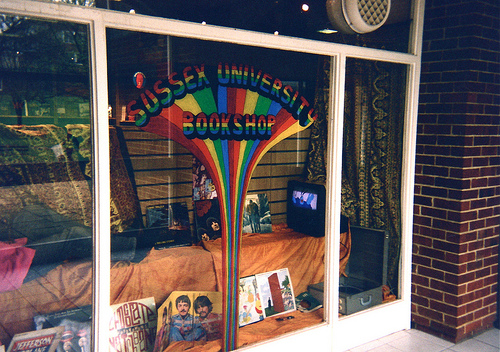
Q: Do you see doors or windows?
A: Yes, there is a window.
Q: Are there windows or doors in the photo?
A: Yes, there is a window.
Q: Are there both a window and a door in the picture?
A: No, there is a window but no doors.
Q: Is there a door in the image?
A: No, there are no doors.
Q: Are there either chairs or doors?
A: No, there are no doors or chairs.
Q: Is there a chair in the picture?
A: No, there are no chairs.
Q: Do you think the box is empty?
A: Yes, the box is empty.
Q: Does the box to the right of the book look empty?
A: Yes, the box is empty.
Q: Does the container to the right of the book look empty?
A: Yes, the box is empty.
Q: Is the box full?
A: No, the box is empty.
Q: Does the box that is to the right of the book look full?
A: No, the box is empty.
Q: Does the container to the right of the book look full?
A: No, the box is empty.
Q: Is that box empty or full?
A: The box is empty.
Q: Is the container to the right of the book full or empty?
A: The box is empty.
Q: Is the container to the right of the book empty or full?
A: The box is empty.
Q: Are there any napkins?
A: No, there are no napkins.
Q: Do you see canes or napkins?
A: No, there are no napkins or canes.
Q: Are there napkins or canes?
A: No, there are no napkins or canes.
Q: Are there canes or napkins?
A: No, there are no napkins or canes.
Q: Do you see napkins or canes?
A: No, there are no napkins or canes.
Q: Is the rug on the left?
A: Yes, the rug is on the left of the image.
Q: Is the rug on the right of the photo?
A: No, the rug is on the left of the image.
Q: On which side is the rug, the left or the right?
A: The rug is on the left of the image.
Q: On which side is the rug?
A: The rug is on the left of the image.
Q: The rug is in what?
A: The rug is in the window.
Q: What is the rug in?
A: The rug is in the window.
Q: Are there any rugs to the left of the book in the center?
A: Yes, there is a rug to the left of the book.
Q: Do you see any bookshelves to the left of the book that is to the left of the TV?
A: No, there is a rug to the left of the book.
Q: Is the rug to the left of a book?
A: Yes, the rug is to the left of a book.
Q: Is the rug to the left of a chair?
A: No, the rug is to the left of a book.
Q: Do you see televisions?
A: Yes, there is a television.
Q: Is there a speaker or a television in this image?
A: Yes, there is a television.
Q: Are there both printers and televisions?
A: No, there is a television but no printers.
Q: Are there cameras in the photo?
A: No, there are no cameras.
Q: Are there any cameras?
A: No, there are no cameras.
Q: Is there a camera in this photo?
A: No, there are no cameras.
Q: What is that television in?
A: The television is in the window.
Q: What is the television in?
A: The television is in the window.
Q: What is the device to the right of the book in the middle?
A: The device is a television.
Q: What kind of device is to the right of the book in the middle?
A: The device is a television.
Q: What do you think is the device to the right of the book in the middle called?
A: The device is a television.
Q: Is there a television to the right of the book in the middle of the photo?
A: Yes, there is a television to the right of the book.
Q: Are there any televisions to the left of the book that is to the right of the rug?
A: No, the television is to the right of the book.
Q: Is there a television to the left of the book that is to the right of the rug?
A: No, the television is to the right of the book.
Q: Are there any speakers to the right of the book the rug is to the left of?
A: No, there is a television to the right of the book.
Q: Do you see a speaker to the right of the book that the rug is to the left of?
A: No, there is a television to the right of the book.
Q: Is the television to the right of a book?
A: Yes, the television is to the right of a book.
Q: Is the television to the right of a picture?
A: No, the television is to the right of a book.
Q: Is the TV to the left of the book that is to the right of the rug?
A: No, the TV is to the right of the book.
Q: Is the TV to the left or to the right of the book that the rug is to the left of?
A: The TV is to the right of the book.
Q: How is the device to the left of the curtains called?
A: The device is a television.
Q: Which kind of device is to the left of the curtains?
A: The device is a television.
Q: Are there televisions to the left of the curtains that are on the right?
A: Yes, there is a television to the left of the curtains.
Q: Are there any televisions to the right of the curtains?
A: No, the television is to the left of the curtains.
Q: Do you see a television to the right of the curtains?
A: No, the television is to the left of the curtains.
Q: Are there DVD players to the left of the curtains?
A: No, there is a television to the left of the curtains.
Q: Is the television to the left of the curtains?
A: Yes, the television is to the left of the curtains.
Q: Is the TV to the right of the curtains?
A: No, the TV is to the left of the curtains.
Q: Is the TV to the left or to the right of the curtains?
A: The TV is to the left of the curtains.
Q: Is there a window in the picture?
A: Yes, there is a window.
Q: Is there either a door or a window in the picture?
A: Yes, there is a window.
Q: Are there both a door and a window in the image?
A: No, there is a window but no doors.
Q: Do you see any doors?
A: No, there are no doors.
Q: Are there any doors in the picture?
A: No, there are no doors.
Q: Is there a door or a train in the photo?
A: No, there are no doors or trains.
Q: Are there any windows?
A: Yes, there is a window.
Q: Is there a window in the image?
A: Yes, there is a window.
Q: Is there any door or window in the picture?
A: Yes, there is a window.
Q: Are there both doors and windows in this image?
A: No, there is a window but no doors.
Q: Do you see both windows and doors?
A: No, there is a window but no doors.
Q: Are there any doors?
A: No, there are no doors.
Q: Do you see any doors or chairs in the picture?
A: No, there are no doors or chairs.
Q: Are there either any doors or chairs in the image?
A: No, there are no doors or chairs.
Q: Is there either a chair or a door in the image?
A: No, there are no doors or chairs.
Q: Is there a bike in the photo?
A: No, there are no bikes.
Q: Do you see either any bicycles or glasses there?
A: No, there are no bicycles or glasses.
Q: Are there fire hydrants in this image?
A: No, there are no fire hydrants.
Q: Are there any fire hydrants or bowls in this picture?
A: No, there are no fire hydrants or bowls.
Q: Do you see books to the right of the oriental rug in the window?
A: Yes, there is a book to the right of the rug.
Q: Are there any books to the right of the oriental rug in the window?
A: Yes, there is a book to the right of the rug.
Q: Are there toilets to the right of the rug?
A: No, there is a book to the right of the rug.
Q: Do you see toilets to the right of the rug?
A: No, there is a book to the right of the rug.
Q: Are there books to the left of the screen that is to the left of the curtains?
A: Yes, there is a book to the left of the screen.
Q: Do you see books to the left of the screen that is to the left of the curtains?
A: Yes, there is a book to the left of the screen.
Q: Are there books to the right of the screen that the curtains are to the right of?
A: No, the book is to the left of the screen.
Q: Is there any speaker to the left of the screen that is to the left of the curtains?
A: No, there is a book to the left of the screen.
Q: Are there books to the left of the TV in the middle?
A: Yes, there is a book to the left of the television.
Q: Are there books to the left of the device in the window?
A: Yes, there is a book to the left of the television.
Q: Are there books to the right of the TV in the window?
A: No, the book is to the left of the television.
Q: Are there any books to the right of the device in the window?
A: No, the book is to the left of the television.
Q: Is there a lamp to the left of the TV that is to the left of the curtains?
A: No, there is a book to the left of the television.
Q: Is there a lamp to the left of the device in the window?
A: No, there is a book to the left of the television.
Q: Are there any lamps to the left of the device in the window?
A: No, there is a book to the left of the television.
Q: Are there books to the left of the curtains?
A: Yes, there is a book to the left of the curtains.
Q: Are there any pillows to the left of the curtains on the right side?
A: No, there is a book to the left of the curtains.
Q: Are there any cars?
A: No, there are no cars.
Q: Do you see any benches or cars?
A: No, there are no cars or benches.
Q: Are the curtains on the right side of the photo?
A: Yes, the curtains are on the right of the image.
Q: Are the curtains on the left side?
A: No, the curtains are on the right of the image.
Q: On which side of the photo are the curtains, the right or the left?
A: The curtains are on the right of the image.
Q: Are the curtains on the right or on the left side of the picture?
A: The curtains are on the right of the image.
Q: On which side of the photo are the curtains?
A: The curtains are on the right of the image.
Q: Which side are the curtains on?
A: The curtains are on the right of the image.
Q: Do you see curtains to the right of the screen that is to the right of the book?
A: Yes, there are curtains to the right of the screen.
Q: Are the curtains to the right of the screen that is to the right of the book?
A: Yes, the curtains are to the right of the screen.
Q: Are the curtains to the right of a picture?
A: No, the curtains are to the right of the screen.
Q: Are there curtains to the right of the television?
A: Yes, there are curtains to the right of the television.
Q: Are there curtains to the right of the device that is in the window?
A: Yes, there are curtains to the right of the television.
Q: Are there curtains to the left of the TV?
A: No, the curtains are to the right of the TV.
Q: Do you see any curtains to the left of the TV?
A: No, the curtains are to the right of the TV.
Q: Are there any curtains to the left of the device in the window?
A: No, the curtains are to the right of the TV.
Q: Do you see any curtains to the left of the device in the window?
A: No, the curtains are to the right of the TV.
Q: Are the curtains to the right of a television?
A: Yes, the curtains are to the right of a television.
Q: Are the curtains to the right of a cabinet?
A: No, the curtains are to the right of a television.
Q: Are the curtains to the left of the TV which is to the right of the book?
A: No, the curtains are to the right of the television.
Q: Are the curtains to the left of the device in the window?
A: No, the curtains are to the right of the television.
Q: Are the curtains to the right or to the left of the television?
A: The curtains are to the right of the television.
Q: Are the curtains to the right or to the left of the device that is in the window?
A: The curtains are to the right of the television.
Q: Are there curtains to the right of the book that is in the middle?
A: Yes, there are curtains to the right of the book.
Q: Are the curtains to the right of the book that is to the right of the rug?
A: Yes, the curtains are to the right of the book.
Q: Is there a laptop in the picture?
A: No, there are no laptops.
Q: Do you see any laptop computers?
A: No, there are no laptop computers.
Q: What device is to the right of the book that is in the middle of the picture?
A: The device is a screen.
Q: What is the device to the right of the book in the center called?
A: The device is a screen.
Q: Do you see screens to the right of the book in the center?
A: Yes, there is a screen to the right of the book.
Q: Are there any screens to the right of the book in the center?
A: Yes, there is a screen to the right of the book.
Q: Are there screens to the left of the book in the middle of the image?
A: No, the screen is to the right of the book.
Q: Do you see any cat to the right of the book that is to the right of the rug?
A: No, there is a screen to the right of the book.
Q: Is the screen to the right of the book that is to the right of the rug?
A: Yes, the screen is to the right of the book.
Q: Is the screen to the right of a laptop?
A: No, the screen is to the right of the book.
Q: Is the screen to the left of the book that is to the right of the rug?
A: No, the screen is to the right of the book.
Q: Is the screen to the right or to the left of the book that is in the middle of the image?
A: The screen is to the right of the book.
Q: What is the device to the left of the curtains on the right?
A: The device is a screen.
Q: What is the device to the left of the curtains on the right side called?
A: The device is a screen.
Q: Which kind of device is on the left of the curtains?
A: The device is a screen.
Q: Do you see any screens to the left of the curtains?
A: Yes, there is a screen to the left of the curtains.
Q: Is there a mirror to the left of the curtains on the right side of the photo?
A: No, there is a screen to the left of the curtains.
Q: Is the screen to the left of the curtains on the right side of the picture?
A: Yes, the screen is to the left of the curtains.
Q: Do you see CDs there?
A: No, there are no cds.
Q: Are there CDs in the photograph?
A: No, there are no cds.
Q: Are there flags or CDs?
A: No, there are no CDs or flags.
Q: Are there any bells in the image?
A: No, there are no bells.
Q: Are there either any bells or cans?
A: No, there are no bells or cans.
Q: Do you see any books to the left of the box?
A: Yes, there is a book to the left of the box.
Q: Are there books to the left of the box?
A: Yes, there is a book to the left of the box.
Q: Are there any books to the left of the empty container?
A: Yes, there is a book to the left of the box.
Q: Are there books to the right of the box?
A: No, the book is to the left of the box.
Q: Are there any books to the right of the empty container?
A: No, the book is to the left of the box.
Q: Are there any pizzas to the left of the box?
A: No, there is a book to the left of the box.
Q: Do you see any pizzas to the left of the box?
A: No, there is a book to the left of the box.